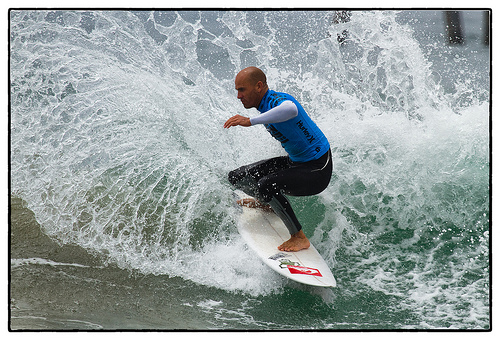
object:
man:
[223, 66, 332, 253]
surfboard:
[227, 187, 337, 288]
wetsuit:
[229, 89, 331, 234]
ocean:
[11, 8, 490, 330]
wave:
[8, 36, 489, 307]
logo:
[287, 263, 322, 277]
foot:
[230, 194, 309, 250]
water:
[11, 11, 481, 331]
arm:
[223, 99, 299, 127]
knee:
[221, 172, 273, 196]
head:
[235, 66, 268, 109]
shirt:
[256, 89, 329, 162]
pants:
[229, 149, 333, 235]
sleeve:
[249, 101, 300, 128]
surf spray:
[43, 9, 488, 298]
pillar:
[438, 9, 466, 47]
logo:
[295, 118, 317, 144]